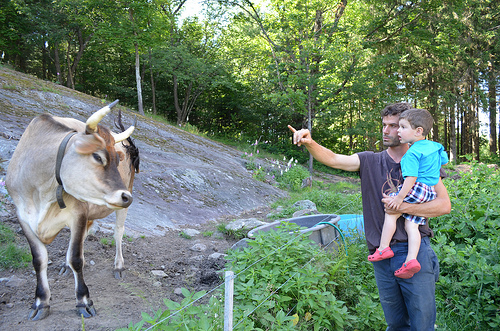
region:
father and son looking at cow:
[378, 99, 438, 151]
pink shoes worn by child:
[365, 237, 422, 281]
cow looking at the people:
[49, 100, 144, 212]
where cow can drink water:
[246, 209, 351, 251]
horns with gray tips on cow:
[87, 95, 145, 142]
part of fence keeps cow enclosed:
[167, 262, 294, 328]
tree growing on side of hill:
[120, 0, 164, 111]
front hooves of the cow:
[19, 295, 110, 325]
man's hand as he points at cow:
[279, 113, 323, 162]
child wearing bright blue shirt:
[395, 106, 447, 179]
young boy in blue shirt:
[370, 105, 449, 283]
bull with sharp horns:
[16, 98, 135, 316]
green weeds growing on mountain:
[246, 246, 355, 326]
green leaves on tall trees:
[225, 12, 357, 106]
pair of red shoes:
[367, 243, 424, 281]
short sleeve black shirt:
[349, 144, 430, 247]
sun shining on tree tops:
[197, 5, 362, 110]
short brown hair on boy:
[395, 107, 436, 140]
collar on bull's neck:
[43, 117, 79, 214]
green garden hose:
[313, 215, 357, 262]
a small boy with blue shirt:
[391, 106, 450, 288]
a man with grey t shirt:
[283, 78, 403, 295]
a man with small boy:
[277, 75, 464, 290]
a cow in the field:
[12, 78, 148, 328]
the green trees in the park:
[201, 46, 304, 105]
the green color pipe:
[305, 210, 355, 292]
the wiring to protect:
[205, 253, 324, 300]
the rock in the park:
[167, 145, 228, 200]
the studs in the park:
[452, 223, 482, 303]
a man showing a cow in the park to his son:
[18, 63, 455, 293]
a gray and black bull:
[11, 97, 145, 322]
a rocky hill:
[3, 55, 353, 289]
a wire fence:
[126, 176, 374, 328]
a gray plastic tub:
[241, 208, 357, 275]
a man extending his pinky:
[281, 97, 450, 327]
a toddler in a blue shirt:
[366, 103, 449, 283]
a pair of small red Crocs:
[359, 238, 421, 285]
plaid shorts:
[391, 177, 436, 224]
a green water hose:
[310, 217, 355, 286]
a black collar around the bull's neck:
[43, 123, 77, 209]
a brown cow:
[16, 82, 176, 329]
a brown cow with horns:
[17, 87, 209, 313]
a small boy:
[375, 110, 470, 291]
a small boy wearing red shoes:
[365, 93, 460, 310]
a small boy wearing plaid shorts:
[371, 101, 461, 315]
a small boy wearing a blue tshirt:
[371, 107, 475, 269]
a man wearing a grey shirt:
[331, 90, 483, 301]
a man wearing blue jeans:
[340, 87, 469, 319]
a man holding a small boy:
[351, 91, 498, 253]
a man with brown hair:
[329, 105, 484, 187]